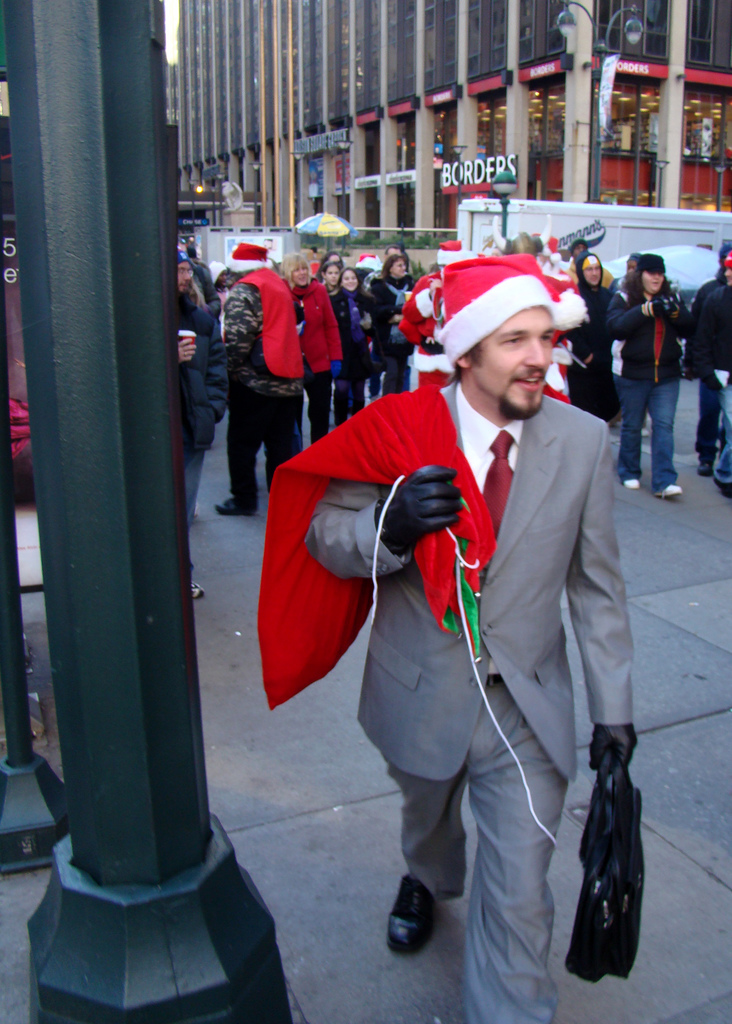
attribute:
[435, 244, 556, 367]
hat — red, white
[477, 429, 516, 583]
tie — red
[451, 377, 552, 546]
shirt — white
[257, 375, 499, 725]
bag — red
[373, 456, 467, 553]
glove — black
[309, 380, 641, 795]
jacket — grey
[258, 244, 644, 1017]
man — holding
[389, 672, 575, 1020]
pants — grey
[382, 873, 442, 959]
shoe — black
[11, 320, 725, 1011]
sidewalk — light grey